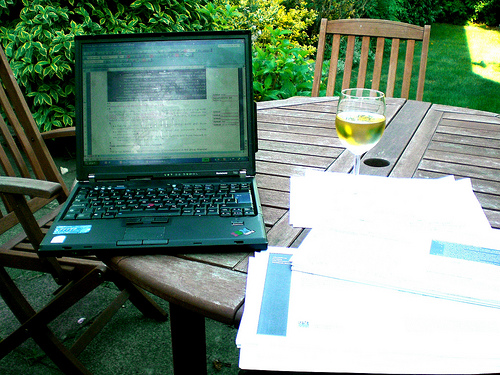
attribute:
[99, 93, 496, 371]
table — wooden, brown, round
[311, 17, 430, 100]
chair — wooden, brown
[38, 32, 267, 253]
laptop — black, open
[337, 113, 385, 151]
wine — white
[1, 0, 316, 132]
bush — green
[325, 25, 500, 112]
grass — green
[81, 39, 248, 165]
screen — on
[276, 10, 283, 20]
flower — yellow